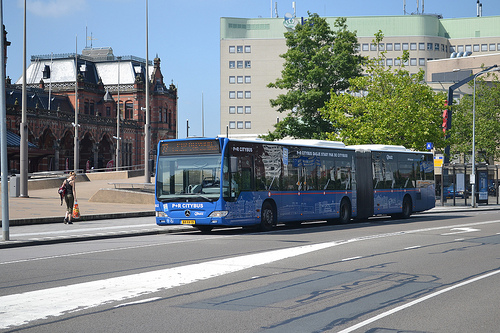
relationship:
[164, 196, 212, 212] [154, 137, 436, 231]
letters on blue bus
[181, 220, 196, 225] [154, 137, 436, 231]
licence plate on blue bus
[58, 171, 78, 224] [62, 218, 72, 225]
person wearing high heels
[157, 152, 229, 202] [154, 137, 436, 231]
window on a blue bus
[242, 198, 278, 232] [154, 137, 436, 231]
wheel on a blue bus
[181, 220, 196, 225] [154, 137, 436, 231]
licence plate on a blue bus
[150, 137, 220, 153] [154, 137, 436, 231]
sign on blue bus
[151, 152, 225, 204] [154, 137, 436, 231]
window on blue bus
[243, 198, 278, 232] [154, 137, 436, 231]
tire on blue bus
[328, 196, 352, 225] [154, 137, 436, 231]
tire on blue bus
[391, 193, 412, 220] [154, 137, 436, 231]
tire on blue bus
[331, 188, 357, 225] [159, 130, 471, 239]
tire on bus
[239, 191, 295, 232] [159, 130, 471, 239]
tire on bus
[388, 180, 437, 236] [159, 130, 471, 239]
tire on bus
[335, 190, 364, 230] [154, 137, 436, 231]
tire on blue bus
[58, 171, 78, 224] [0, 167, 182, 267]
person walking on street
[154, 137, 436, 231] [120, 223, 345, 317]
blue bus on road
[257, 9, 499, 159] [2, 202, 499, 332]
trees next to street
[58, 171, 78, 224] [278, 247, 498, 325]
person walking on road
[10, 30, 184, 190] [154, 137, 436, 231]
building behind blue bus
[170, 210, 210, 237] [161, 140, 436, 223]
licence plate on bus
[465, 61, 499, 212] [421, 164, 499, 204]
post on sidewalk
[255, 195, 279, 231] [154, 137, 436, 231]
wheel on blue bus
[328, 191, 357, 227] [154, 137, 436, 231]
wheel on blue bus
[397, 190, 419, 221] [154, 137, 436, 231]
wheel on blue bus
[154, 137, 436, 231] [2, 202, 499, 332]
blue bus on street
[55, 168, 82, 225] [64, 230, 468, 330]
person on road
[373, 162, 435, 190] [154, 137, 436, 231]
window on blue bus